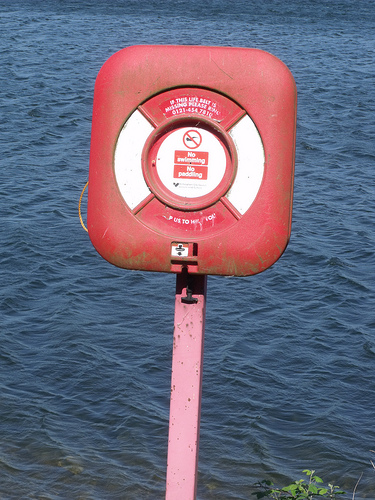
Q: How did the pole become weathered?
A: Wind and water.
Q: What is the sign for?
A: No swimming.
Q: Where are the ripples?
A: In the water.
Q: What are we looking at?
A: A sign.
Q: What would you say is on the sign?
A: Red and white and no swimming.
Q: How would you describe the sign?
A: Red white and square.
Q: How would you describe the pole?
A: Pink.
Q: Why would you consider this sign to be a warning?
A: No swimming no paddling.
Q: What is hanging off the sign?
A: Yellow rope.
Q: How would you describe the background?
A: Water.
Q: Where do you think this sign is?
A: On water.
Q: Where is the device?
A: On pole.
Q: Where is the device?
A: Near water.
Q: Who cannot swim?
A: People.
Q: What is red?
A: Sign.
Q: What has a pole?
A: The sign.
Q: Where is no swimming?
A: On the sign.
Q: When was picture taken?
A: Daytime.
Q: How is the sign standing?
A: In soil.